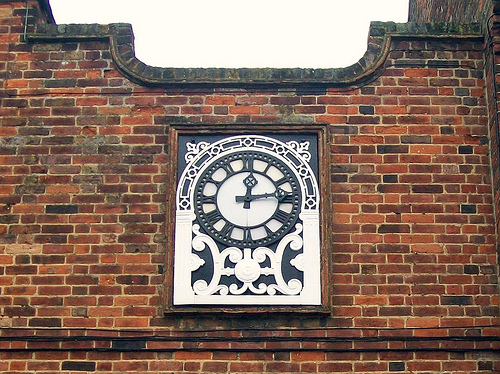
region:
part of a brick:
[378, 216, 385, 253]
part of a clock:
[311, 261, 323, 290]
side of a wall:
[370, 261, 384, 282]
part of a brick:
[368, 221, 388, 258]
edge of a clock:
[266, 223, 281, 260]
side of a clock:
[201, 246, 229, 299]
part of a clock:
[242, 255, 258, 268]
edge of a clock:
[226, 203, 256, 270]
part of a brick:
[413, 170, 423, 183]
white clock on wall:
[184, 123, 321, 304]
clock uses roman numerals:
[183, 143, 330, 251]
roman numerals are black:
[206, 168, 296, 244]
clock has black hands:
[216, 164, 295, 241]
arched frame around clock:
[176, 131, 298, 297]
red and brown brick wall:
[303, 56, 464, 329]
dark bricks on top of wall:
[61, 13, 397, 93]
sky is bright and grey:
[191, 3, 332, 58]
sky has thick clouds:
[206, 26, 361, 68]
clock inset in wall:
[164, 113, 351, 336]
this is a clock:
[169, 137, 315, 282]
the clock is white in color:
[175, 130, 316, 293]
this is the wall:
[353, 92, 469, 292]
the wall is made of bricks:
[341, 115, 471, 292]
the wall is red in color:
[348, 120, 458, 296]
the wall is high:
[349, 74, 489, 344]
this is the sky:
[203, 0, 296, 59]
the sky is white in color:
[228, 21, 309, 53]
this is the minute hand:
[260, 184, 288, 201]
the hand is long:
[256, 188, 290, 203]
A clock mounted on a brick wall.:
[0, 22, 498, 370]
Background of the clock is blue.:
[176, 130, 321, 301]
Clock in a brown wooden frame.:
[162, 120, 330, 313]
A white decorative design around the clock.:
[175, 135, 316, 305]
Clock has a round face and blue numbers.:
[195, 150, 301, 245]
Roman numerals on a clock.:
[201, 153, 294, 248]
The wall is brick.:
[0, 2, 496, 369]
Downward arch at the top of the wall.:
[18, 10, 479, 85]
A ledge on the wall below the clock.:
[0, 315, 498, 340]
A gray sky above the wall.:
[26, 0, 490, 75]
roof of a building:
[33, 1, 498, 67]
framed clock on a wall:
[158, 105, 328, 332]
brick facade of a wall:
[379, 106, 469, 316]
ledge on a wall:
[11, 308, 483, 358]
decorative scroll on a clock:
[195, 240, 308, 300]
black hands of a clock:
[233, 169, 300, 206]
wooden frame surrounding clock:
[161, 109, 188, 324]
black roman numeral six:
[236, 217, 253, 257]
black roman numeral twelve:
[236, 148, 257, 178]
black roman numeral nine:
[193, 186, 220, 206]